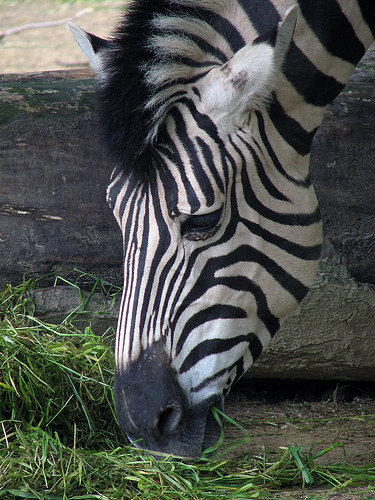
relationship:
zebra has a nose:
[61, 5, 340, 448] [110, 370, 211, 448]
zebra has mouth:
[61, 5, 340, 448] [196, 395, 217, 453]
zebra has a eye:
[61, 5, 340, 448] [176, 208, 223, 242]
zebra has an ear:
[61, 5, 340, 448] [239, 6, 318, 75]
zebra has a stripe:
[61, 5, 340, 448] [273, 103, 297, 137]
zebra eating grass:
[61, 5, 340, 448] [30, 334, 89, 402]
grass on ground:
[30, 334, 89, 402] [11, 445, 97, 492]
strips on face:
[224, 143, 290, 186] [105, 167, 329, 388]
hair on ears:
[217, 50, 264, 97] [68, 3, 311, 104]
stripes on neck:
[153, 159, 239, 195] [280, 53, 318, 162]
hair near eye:
[191, 198, 222, 214] [176, 208, 223, 242]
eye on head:
[176, 208, 223, 242] [60, 9, 347, 168]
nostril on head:
[154, 393, 184, 440] [60, 9, 347, 168]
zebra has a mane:
[61, 5, 340, 448] [109, 30, 182, 102]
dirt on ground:
[312, 327, 355, 380] [11, 445, 97, 492]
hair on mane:
[217, 50, 264, 97] [109, 30, 182, 102]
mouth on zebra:
[196, 395, 217, 453] [61, 5, 340, 448]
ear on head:
[239, 6, 318, 75] [60, 9, 347, 168]